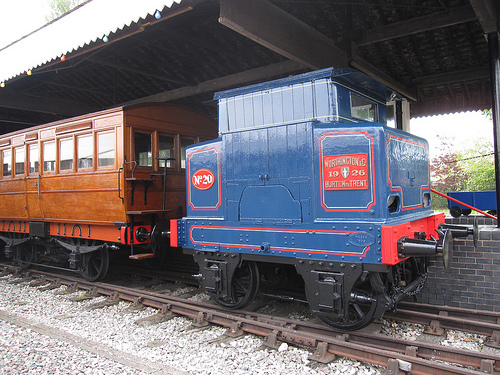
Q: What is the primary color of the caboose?
A: Blue.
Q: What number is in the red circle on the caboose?
A: 20.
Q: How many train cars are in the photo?
A: Two.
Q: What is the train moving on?
A: Train tracks.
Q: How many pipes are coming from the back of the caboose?
A: 2.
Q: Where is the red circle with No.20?
A: On the caboose.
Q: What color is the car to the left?
A: Brown.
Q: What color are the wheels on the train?
A: Black.